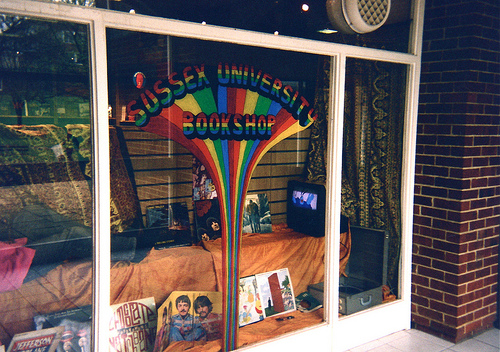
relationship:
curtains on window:
[316, 63, 399, 231] [1, 0, 422, 348]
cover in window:
[139, 200, 197, 250] [100, 21, 330, 350]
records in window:
[111, 266, 295, 350] [100, 21, 330, 350]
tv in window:
[284, 178, 325, 238] [100, 21, 330, 350]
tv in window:
[284, 178, 325, 238] [341, 56, 409, 315]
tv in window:
[284, 178, 325, 238] [1, 12, 98, 350]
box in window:
[297, 209, 407, 315] [1, 0, 422, 348]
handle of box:
[360, 295, 372, 305] [307, 222, 391, 314]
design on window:
[117, 53, 322, 350] [1, 0, 422, 348]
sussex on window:
[125, 64, 209, 128] [1, 0, 422, 348]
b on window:
[170, 109, 207, 150] [28, 32, 406, 335]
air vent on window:
[340, 0, 394, 35] [1, 0, 422, 348]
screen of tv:
[294, 193, 316, 210] [287, 181, 322, 231]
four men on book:
[155, 296, 223, 349] [136, 280, 227, 341]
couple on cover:
[246, 199, 262, 232] [240, 192, 270, 234]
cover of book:
[240, 192, 270, 234] [242, 192, 272, 236]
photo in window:
[146, 287, 227, 350] [336, 49, 414, 309]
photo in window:
[251, 269, 301, 319] [100, 21, 330, 350]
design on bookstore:
[117, 53, 322, 350] [0, 0, 425, 352]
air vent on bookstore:
[340, 0, 393, 30] [0, 0, 425, 352]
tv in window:
[284, 178, 325, 238] [101, 36, 343, 349]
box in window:
[306, 226, 390, 315] [1, 0, 422, 348]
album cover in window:
[193, 197, 222, 244] [100, 21, 330, 350]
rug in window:
[1, 120, 145, 252] [100, 21, 330, 350]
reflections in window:
[0, 51, 97, 256] [39, 12, 442, 349]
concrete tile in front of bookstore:
[383, 324, 448, 349] [0, 0, 425, 352]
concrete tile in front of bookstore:
[441, 334, 496, 349] [0, 0, 425, 352]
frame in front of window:
[371, 34, 423, 253] [101, 36, 343, 349]